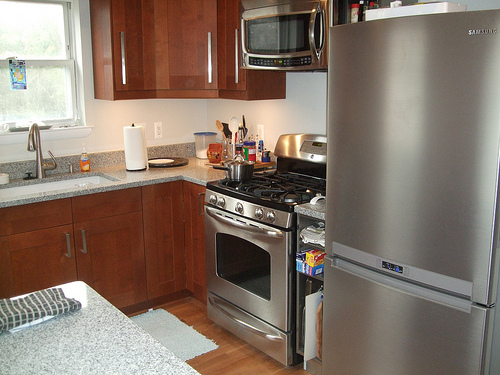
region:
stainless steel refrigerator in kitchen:
[317, 10, 497, 373]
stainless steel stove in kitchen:
[202, 131, 327, 366]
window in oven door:
[216, 231, 270, 299]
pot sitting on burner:
[205, 158, 253, 183]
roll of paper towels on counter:
[123, 122, 148, 169]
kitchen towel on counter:
[0, 286, 80, 333]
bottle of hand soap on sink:
[77, 144, 91, 173]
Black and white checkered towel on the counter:
[0, 285, 82, 330]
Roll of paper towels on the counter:
[122, 120, 149, 170]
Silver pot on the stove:
[213, 161, 252, 184]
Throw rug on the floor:
[124, 305, 218, 359]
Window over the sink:
[0, 1, 88, 136]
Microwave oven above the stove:
[239, 0, 324, 74]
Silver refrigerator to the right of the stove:
[323, 13, 495, 370]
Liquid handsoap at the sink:
[78, 143, 90, 174]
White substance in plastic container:
[194, 126, 219, 161]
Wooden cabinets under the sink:
[0, 177, 217, 312]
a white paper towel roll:
[123, 122, 152, 170]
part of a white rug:
[130, 308, 217, 358]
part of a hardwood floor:
[171, 298, 293, 373]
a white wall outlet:
[152, 120, 166, 139]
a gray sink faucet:
[25, 123, 51, 174]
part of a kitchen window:
[0, 0, 78, 127]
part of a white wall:
[278, 70, 325, 131]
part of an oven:
[203, 134, 330, 359]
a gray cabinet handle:
[78, 224, 93, 254]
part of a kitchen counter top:
[0, 282, 183, 374]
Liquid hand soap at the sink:
[78, 145, 92, 182]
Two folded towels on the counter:
[0, 278, 92, 335]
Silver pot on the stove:
[211, 156, 252, 187]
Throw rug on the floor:
[128, 306, 218, 358]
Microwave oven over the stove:
[237, 0, 324, 77]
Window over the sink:
[0, 0, 80, 135]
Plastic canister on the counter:
[194, 128, 215, 160]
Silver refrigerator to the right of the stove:
[303, 14, 498, 373]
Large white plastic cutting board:
[303, 287, 322, 365]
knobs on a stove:
[205, 187, 230, 207]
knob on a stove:
[245, 200, 265, 220]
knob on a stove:
[260, 205, 275, 225]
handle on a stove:
[201, 295, 278, 345]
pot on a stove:
[196, 151, 251, 182]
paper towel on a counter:
[111, 122, 161, 175]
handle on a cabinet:
[58, 220, 94, 265]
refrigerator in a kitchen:
[324, 26, 499, 368]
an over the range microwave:
[235, 6, 326, 73]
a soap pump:
[77, 148, 90, 170]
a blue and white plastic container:
[192, 128, 219, 160]